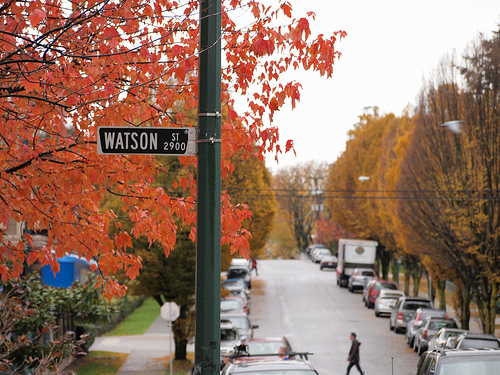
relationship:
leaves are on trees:
[333, 153, 477, 237] [323, 66, 499, 277]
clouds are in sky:
[352, 14, 424, 80] [218, 2, 463, 165]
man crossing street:
[336, 328, 375, 374] [262, 237, 427, 373]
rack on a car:
[228, 345, 312, 365] [220, 350, 326, 375]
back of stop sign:
[158, 299, 183, 321] [157, 297, 189, 374]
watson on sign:
[99, 133, 162, 150] [93, 125, 206, 159]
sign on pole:
[93, 125, 206, 159] [194, 2, 237, 370]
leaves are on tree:
[37, 43, 183, 116] [1, 4, 257, 264]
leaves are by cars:
[333, 153, 477, 237] [320, 245, 499, 375]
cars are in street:
[320, 245, 499, 375] [262, 237, 427, 373]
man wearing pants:
[336, 328, 375, 374] [346, 362, 365, 375]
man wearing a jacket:
[336, 328, 375, 374] [339, 341, 370, 364]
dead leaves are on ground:
[162, 355, 194, 370] [157, 346, 207, 374]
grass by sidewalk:
[69, 294, 168, 375] [97, 306, 197, 374]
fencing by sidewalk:
[18, 305, 86, 374] [97, 306, 197, 374]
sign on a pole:
[93, 125, 206, 159] [194, 2, 237, 370]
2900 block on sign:
[161, 141, 190, 155] [93, 125, 206, 159]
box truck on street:
[333, 234, 381, 282] [262, 237, 427, 373]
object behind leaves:
[44, 254, 100, 288] [37, 43, 183, 116]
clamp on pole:
[195, 104, 229, 151] [194, 2, 237, 370]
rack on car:
[228, 345, 312, 365] [220, 350, 326, 375]